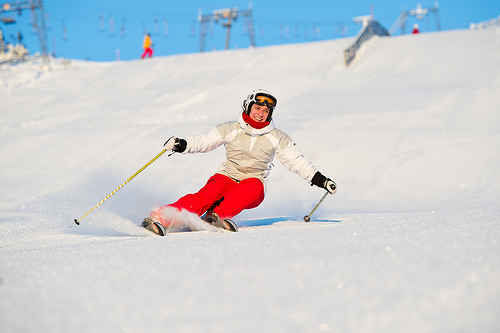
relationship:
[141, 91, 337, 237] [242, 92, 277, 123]
woman wearing helmet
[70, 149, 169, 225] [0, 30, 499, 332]
ski pole in snow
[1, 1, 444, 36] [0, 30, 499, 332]
ski lift on snow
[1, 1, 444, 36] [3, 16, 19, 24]
ski lift has chairs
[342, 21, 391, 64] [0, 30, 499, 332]
fence on snow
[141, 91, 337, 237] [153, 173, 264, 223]
woman has pants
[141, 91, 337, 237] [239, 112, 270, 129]
woman wearing scarf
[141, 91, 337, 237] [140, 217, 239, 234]
woman has skis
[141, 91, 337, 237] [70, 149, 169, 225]
woman holding ski pole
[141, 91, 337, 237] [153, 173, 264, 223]
woman wearing pants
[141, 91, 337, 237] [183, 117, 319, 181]
woman wearing jacket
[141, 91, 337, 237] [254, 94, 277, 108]
woman wearing goggles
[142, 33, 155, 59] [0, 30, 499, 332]
person on snow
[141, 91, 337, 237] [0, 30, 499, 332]
woman on snow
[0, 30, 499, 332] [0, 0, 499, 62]
snow under sky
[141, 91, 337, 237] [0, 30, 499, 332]
woman skiing in snow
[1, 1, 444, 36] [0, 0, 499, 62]
ski lift in front of sky